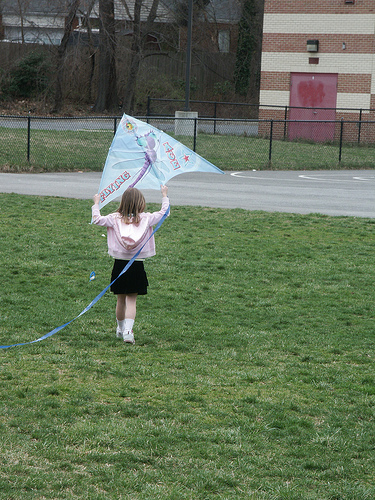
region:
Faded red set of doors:
[288, 71, 336, 145]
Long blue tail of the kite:
[0, 200, 171, 354]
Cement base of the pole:
[172, 107, 199, 136]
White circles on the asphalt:
[227, 159, 374, 191]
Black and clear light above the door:
[302, 38, 321, 52]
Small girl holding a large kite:
[73, 106, 224, 349]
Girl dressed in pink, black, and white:
[78, 175, 184, 345]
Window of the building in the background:
[214, 30, 232, 53]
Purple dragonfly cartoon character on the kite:
[121, 124, 165, 197]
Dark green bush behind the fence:
[0, 48, 53, 106]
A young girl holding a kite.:
[46, 113, 229, 347]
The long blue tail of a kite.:
[5, 210, 184, 376]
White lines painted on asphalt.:
[226, 162, 369, 211]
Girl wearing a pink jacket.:
[85, 184, 177, 259]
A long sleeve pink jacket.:
[88, 194, 180, 268]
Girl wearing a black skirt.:
[79, 192, 170, 300]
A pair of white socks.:
[110, 309, 142, 334]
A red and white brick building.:
[255, 4, 372, 136]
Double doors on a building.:
[282, 67, 347, 140]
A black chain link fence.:
[12, 106, 367, 172]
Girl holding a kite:
[26, 73, 255, 378]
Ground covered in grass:
[15, 341, 362, 486]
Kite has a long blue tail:
[7, 260, 130, 354]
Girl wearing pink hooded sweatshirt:
[79, 198, 183, 259]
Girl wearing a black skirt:
[96, 256, 164, 303]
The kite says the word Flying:
[86, 165, 139, 200]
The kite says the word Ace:
[160, 134, 184, 179]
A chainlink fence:
[16, 106, 357, 164]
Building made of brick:
[258, 9, 371, 129]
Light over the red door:
[296, 26, 324, 58]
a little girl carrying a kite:
[84, 108, 230, 349]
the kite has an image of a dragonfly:
[106, 128, 170, 186]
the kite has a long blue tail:
[2, 189, 173, 351]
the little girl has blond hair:
[115, 185, 147, 226]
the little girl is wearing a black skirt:
[106, 255, 153, 297]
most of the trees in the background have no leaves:
[2, 0, 257, 116]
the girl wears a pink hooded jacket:
[89, 193, 174, 265]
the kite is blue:
[88, 109, 229, 211]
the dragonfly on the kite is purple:
[109, 127, 173, 191]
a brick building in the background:
[259, 2, 374, 148]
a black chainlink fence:
[222, 116, 354, 169]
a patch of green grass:
[226, 255, 361, 421]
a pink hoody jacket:
[88, 204, 172, 259]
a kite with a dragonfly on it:
[85, 109, 232, 216]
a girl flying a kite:
[78, 110, 228, 343]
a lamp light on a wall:
[302, 37, 321, 54]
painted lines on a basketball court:
[227, 167, 370, 192]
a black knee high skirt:
[106, 257, 152, 299]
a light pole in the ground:
[170, 3, 201, 138]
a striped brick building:
[264, 6, 373, 149]